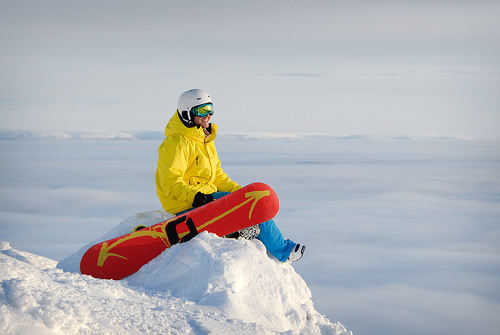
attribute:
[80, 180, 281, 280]
snowboard — red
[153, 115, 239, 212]
jacket — yellow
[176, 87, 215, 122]
helmet — white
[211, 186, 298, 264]
pants — blue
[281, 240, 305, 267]
shoe — white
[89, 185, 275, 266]
design — black and yellow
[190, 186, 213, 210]
glove — black